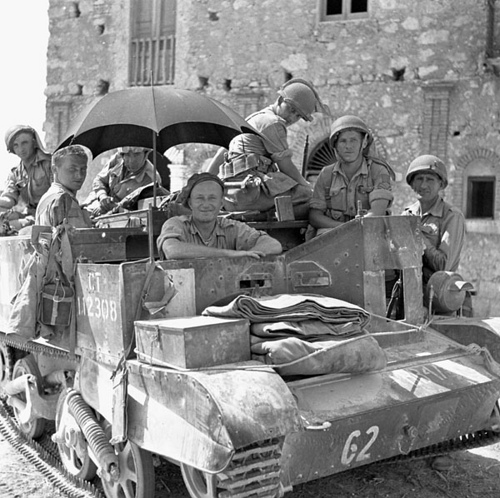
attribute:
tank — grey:
[1, 202, 497, 497]